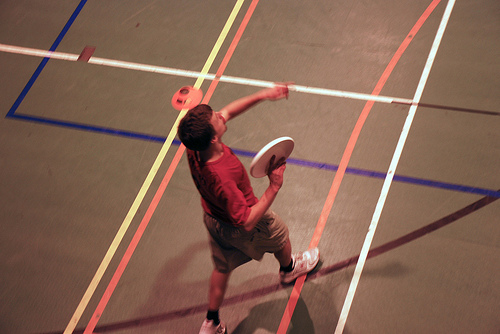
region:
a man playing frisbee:
[174, 81, 319, 331]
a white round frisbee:
[249, 135, 293, 180]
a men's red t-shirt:
[184, 138, 256, 232]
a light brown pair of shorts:
[198, 208, 291, 271]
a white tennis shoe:
[279, 248, 318, 285]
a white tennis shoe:
[194, 318, 223, 332]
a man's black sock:
[277, 259, 293, 274]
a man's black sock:
[205, 306, 221, 324]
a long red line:
[274, 0, 439, 330]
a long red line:
[79, 0, 254, 332]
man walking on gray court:
[164, 79, 325, 326]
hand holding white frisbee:
[237, 126, 299, 185]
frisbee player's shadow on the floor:
[123, 230, 393, 331]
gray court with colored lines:
[7, 4, 499, 321]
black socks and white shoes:
[200, 246, 321, 332]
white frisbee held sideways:
[245, 136, 294, 178]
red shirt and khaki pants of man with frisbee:
[182, 144, 297, 269]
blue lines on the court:
[5, 6, 492, 206]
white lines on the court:
[5, 0, 465, 330]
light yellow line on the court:
[56, 35, 230, 332]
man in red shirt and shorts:
[177, 85, 320, 331]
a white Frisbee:
[250, 131, 292, 176]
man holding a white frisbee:
[180, 79, 319, 332]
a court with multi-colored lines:
[5, 8, 486, 331]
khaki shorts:
[203, 210, 286, 266]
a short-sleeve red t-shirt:
[185, 147, 257, 222]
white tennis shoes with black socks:
[200, 250, 318, 332]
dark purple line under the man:
[1, 194, 498, 329]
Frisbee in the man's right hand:
[250, 138, 292, 184]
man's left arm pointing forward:
[215, 78, 293, 115]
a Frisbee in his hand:
[250, 133, 297, 181]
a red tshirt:
[171, 147, 262, 229]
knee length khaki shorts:
[200, 206, 291, 273]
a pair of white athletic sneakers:
[194, 245, 323, 332]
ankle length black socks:
[200, 257, 295, 324]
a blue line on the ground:
[6, 0, 497, 200]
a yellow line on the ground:
[61, 2, 241, 332]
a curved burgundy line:
[0, 193, 498, 332]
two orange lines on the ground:
[82, 0, 441, 332]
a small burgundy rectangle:
[76, 40, 96, 64]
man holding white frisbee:
[151, 78, 322, 332]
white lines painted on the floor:
[0, 1, 456, 332]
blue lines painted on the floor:
[5, 5, 499, 205]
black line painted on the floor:
[68, 193, 493, 330]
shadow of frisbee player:
[112, 226, 412, 332]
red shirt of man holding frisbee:
[175, 145, 261, 218]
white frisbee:
[245, 135, 290, 180]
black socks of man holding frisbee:
[202, 255, 302, 322]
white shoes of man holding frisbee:
[201, 250, 322, 332]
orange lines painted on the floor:
[75, 0, 450, 332]